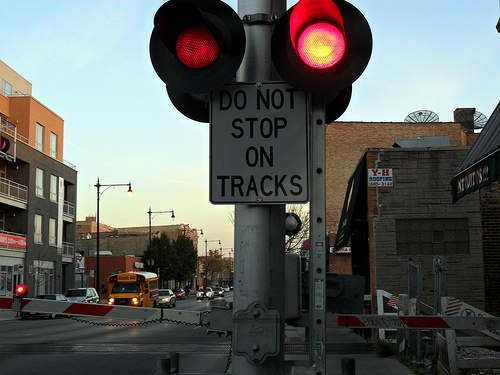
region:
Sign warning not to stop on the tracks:
[202, 88, 312, 207]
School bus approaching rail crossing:
[108, 270, 160, 305]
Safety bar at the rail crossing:
[16, 275, 227, 374]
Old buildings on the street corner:
[3, 91, 85, 286]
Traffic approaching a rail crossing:
[79, 191, 224, 301]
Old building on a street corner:
[359, 147, 479, 292]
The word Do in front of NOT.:
[217, 89, 247, 113]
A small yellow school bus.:
[106, 271, 159, 308]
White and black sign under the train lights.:
[207, 82, 309, 204]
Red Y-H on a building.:
[369, 168, 391, 178]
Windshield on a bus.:
[110, 279, 141, 294]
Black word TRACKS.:
[215, 174, 303, 196]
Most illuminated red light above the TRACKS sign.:
[297, 21, 345, 70]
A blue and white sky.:
[2, 0, 498, 225]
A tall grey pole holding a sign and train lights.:
[234, 1, 284, 373]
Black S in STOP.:
[230, 115, 245, 139]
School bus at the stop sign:
[103, 267, 164, 313]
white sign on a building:
[361, 164, 401, 189]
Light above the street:
[119, 185, 140, 195]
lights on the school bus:
[105, 295, 141, 306]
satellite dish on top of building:
[396, 93, 442, 126]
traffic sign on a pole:
[191, 64, 321, 230]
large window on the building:
[33, 118, 48, 153]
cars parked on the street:
[14, 278, 105, 321]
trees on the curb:
[140, 226, 205, 293]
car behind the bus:
[153, 281, 183, 302]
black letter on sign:
[207, 82, 234, 113]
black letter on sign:
[231, 81, 251, 115]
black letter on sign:
[251, 73, 273, 110]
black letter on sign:
[264, 86, 285, 108]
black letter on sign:
[285, 85, 305, 110]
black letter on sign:
[225, 113, 245, 138]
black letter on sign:
[244, 109, 258, 136]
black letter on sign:
[272, 111, 290, 136]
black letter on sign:
[234, 138, 259, 168]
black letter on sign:
[260, 143, 284, 170]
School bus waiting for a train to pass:
[100, 263, 165, 321]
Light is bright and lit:
[281, 0, 368, 89]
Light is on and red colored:
[285, 2, 361, 93]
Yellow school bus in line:
[103, 261, 165, 311]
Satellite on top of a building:
[399, 101, 442, 133]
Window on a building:
[32, 161, 47, 199]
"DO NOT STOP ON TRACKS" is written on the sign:
[214, 85, 309, 205]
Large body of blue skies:
[43, 14, 123, 82]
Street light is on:
[88, 170, 143, 207]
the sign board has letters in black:
[209, 83, 310, 203]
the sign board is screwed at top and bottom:
[208, 80, 312, 205]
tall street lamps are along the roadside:
[93, 177, 231, 319]